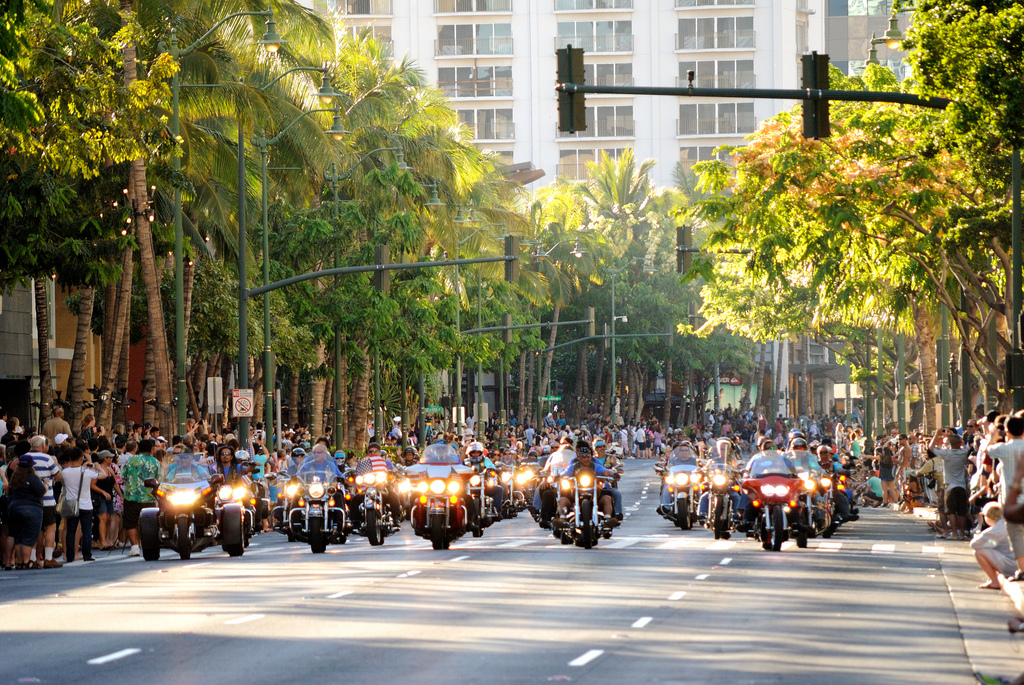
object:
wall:
[635, 6, 678, 183]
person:
[633, 423, 650, 458]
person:
[985, 412, 1021, 577]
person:
[928, 432, 980, 537]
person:
[890, 432, 918, 509]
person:
[868, 437, 903, 504]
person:
[57, 441, 104, 561]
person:
[20, 433, 72, 570]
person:
[8, 456, 51, 568]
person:
[120, 432, 163, 551]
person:
[41, 410, 76, 464]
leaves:
[703, 162, 731, 196]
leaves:
[662, 204, 709, 231]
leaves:
[830, 296, 876, 327]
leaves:
[868, 251, 904, 293]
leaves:
[751, 301, 794, 346]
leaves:
[829, 346, 862, 376]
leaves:
[384, 209, 412, 249]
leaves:
[451, 159, 505, 203]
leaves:
[581, 151, 620, 201]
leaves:
[484, 276, 523, 319]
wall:
[507, 4, 559, 183]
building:
[0, 0, 345, 536]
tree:
[673, 99, 1021, 418]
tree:
[707, 90, 1016, 522]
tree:
[20, 6, 159, 453]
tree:
[312, 21, 403, 493]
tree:
[213, 11, 303, 441]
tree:
[550, 148, 689, 430]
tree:
[410, 132, 497, 449]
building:
[282, 0, 952, 260]